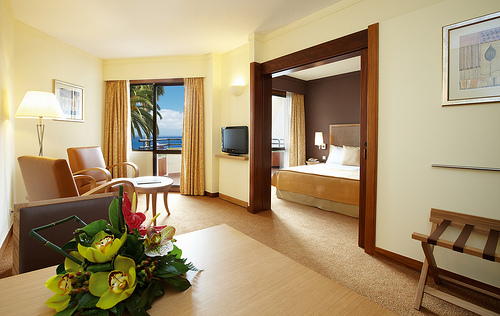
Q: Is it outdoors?
A: Yes, it is outdoors.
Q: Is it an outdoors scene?
A: Yes, it is outdoors.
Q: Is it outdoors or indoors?
A: It is outdoors.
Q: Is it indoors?
A: No, it is outdoors.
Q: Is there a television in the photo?
A: Yes, there is a television.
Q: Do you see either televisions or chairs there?
A: Yes, there is a television.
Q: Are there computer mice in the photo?
A: No, there are no computer mice.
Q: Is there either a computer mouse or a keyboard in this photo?
A: No, there are no computer mice or keyboards.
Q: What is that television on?
A: The television is on the wall.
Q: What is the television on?
A: The television is on the wall.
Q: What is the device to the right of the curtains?
A: The device is a television.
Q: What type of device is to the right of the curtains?
A: The device is a television.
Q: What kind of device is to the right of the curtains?
A: The device is a television.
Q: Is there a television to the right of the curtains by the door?
A: Yes, there is a television to the right of the curtains.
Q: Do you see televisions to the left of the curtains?
A: No, the television is to the right of the curtains.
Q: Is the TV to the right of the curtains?
A: Yes, the TV is to the right of the curtains.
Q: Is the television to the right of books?
A: No, the television is to the right of the curtains.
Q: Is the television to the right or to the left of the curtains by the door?
A: The television is to the right of the curtains.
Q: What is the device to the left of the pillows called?
A: The device is a television.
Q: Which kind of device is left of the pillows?
A: The device is a television.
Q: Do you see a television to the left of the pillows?
A: Yes, there is a television to the left of the pillows.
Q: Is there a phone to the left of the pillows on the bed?
A: No, there is a television to the left of the pillows.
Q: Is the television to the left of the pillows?
A: Yes, the television is to the left of the pillows.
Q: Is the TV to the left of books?
A: No, the TV is to the left of the pillows.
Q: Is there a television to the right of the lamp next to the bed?
A: No, the television is to the left of the lamp.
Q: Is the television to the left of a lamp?
A: Yes, the television is to the left of a lamp.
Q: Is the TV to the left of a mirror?
A: No, the TV is to the left of a lamp.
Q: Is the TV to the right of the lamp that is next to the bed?
A: No, the TV is to the left of the lamp.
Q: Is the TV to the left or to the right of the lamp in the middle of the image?
A: The TV is to the left of the lamp.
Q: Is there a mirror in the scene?
A: No, there are no mirrors.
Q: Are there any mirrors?
A: No, there are no mirrors.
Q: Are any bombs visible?
A: No, there are no bombs.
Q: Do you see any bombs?
A: No, there are no bombs.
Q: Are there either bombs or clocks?
A: No, there are no bombs or clocks.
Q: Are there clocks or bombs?
A: No, there are no bombs or clocks.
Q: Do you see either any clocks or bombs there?
A: No, there are no bombs or clocks.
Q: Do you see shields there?
A: No, there are no shields.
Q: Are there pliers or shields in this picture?
A: No, there are no shields or pliers.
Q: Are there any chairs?
A: Yes, there is a chair.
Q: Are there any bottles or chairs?
A: Yes, there is a chair.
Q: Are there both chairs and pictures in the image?
A: Yes, there are both a chair and a picture.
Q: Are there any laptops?
A: No, there are no laptops.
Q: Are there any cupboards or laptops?
A: No, there are no laptops or cupboards.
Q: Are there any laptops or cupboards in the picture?
A: No, there are no laptops or cupboards.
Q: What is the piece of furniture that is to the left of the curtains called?
A: The piece of furniture is a chair.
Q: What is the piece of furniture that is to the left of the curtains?
A: The piece of furniture is a chair.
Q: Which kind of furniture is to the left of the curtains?
A: The piece of furniture is a chair.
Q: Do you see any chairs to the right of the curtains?
A: No, the chair is to the left of the curtains.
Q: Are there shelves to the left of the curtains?
A: No, there is a chair to the left of the curtains.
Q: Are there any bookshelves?
A: No, there are no bookshelves.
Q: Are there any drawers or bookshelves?
A: No, there are no bookshelves or drawers.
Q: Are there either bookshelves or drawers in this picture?
A: No, there are no bookshelves or drawers.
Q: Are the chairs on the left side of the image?
A: Yes, the chairs are on the left of the image.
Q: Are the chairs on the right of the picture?
A: No, the chairs are on the left of the image.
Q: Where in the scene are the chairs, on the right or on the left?
A: The chairs are on the left of the image.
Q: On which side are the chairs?
A: The chairs are on the left of the image.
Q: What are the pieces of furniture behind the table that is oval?
A: The pieces of furniture are chairs.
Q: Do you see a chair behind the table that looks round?
A: Yes, there are chairs behind the table.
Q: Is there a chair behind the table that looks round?
A: Yes, there are chairs behind the table.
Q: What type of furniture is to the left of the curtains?
A: The pieces of furniture are chairs.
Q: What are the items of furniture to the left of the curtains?
A: The pieces of furniture are chairs.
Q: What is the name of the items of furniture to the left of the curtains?
A: The pieces of furniture are chairs.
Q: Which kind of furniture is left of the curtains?
A: The pieces of furniture are chairs.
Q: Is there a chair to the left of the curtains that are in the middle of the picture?
A: Yes, there are chairs to the left of the curtains.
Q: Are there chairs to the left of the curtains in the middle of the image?
A: Yes, there are chairs to the left of the curtains.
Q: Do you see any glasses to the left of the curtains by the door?
A: No, there are chairs to the left of the curtains.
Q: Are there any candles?
A: No, there are no candles.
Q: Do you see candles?
A: No, there are no candles.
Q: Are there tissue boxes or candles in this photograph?
A: No, there are no candles or tissue boxes.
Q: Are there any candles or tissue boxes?
A: No, there are no candles or tissue boxes.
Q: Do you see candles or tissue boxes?
A: No, there are no candles or tissue boxes.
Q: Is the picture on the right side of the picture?
A: Yes, the picture is on the right of the image.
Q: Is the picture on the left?
A: No, the picture is on the right of the image.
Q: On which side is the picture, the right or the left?
A: The picture is on the right of the image.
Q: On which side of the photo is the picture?
A: The picture is on the right of the image.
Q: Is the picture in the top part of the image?
A: Yes, the picture is in the top of the image.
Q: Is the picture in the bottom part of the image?
A: No, the picture is in the top of the image.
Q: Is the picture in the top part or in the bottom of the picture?
A: The picture is in the top of the image.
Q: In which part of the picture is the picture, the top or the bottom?
A: The picture is in the top of the image.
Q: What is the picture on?
A: The picture is on the wall.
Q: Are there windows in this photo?
A: Yes, there is a window.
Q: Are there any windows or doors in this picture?
A: Yes, there is a window.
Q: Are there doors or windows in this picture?
A: Yes, there is a window.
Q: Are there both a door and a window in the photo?
A: Yes, there are both a window and a door.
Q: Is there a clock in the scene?
A: No, there are no clocks.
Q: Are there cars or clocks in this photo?
A: No, there are no clocks or cars.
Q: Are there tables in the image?
A: Yes, there is a table.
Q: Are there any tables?
A: Yes, there is a table.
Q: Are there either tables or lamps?
A: Yes, there is a table.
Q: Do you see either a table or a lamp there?
A: Yes, there is a table.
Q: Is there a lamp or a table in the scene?
A: Yes, there is a table.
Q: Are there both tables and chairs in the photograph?
A: Yes, there are both a table and a chair.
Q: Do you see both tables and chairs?
A: Yes, there are both a table and a chair.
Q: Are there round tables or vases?
A: Yes, there is a round table.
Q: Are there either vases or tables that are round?
A: Yes, the table is round.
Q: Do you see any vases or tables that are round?
A: Yes, the table is round.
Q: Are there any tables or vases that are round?
A: Yes, the table is round.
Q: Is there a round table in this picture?
A: Yes, there is a round table.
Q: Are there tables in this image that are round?
A: Yes, there is a table that is round.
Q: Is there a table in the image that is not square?
A: Yes, there is a round table.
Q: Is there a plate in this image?
A: No, there are no plates.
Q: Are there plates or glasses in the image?
A: No, there are no plates or glasses.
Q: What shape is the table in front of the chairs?
A: The table is round.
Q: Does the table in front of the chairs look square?
A: No, the table is round.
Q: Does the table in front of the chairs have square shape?
A: No, the table is round.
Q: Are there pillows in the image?
A: Yes, there are pillows.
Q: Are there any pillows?
A: Yes, there are pillows.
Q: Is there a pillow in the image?
A: Yes, there are pillows.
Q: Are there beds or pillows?
A: Yes, there are pillows.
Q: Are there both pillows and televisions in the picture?
A: Yes, there are both pillows and a television.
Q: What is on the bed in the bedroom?
A: The pillows are on the bed.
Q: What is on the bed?
A: The pillows are on the bed.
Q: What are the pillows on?
A: The pillows are on the bed.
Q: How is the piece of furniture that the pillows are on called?
A: The piece of furniture is a bed.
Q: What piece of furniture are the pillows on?
A: The pillows are on the bed.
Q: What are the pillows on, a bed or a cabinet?
A: The pillows are on a bed.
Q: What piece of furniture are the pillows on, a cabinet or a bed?
A: The pillows are on a bed.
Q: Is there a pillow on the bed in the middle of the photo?
A: Yes, there are pillows on the bed.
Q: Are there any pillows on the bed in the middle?
A: Yes, there are pillows on the bed.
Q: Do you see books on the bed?
A: No, there are pillows on the bed.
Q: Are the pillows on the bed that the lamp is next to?
A: Yes, the pillows are on the bed.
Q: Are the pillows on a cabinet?
A: No, the pillows are on the bed.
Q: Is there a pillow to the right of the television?
A: Yes, there are pillows to the right of the television.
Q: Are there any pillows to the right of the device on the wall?
A: Yes, there are pillows to the right of the television.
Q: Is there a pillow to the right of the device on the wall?
A: Yes, there are pillows to the right of the television.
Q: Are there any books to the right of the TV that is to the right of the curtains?
A: No, there are pillows to the right of the television.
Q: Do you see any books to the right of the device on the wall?
A: No, there are pillows to the right of the television.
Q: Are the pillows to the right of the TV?
A: Yes, the pillows are to the right of the TV.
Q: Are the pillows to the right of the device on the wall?
A: Yes, the pillows are to the right of the TV.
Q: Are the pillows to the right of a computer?
A: No, the pillows are to the right of the TV.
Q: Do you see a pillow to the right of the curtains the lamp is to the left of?
A: Yes, there are pillows to the right of the curtains.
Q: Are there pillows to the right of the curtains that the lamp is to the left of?
A: Yes, there are pillows to the right of the curtains.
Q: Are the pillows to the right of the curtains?
A: Yes, the pillows are to the right of the curtains.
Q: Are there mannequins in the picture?
A: No, there are no mannequins.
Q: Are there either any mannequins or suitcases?
A: No, there are no mannequins or suitcases.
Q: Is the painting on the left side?
A: Yes, the painting is on the left of the image.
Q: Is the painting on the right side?
A: No, the painting is on the left of the image.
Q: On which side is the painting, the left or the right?
A: The painting is on the left of the image.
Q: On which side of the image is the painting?
A: The painting is on the left of the image.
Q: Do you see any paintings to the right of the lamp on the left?
A: Yes, there is a painting to the right of the lamp.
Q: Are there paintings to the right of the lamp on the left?
A: Yes, there is a painting to the right of the lamp.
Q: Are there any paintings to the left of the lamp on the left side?
A: No, the painting is to the right of the lamp.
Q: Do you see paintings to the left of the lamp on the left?
A: No, the painting is to the right of the lamp.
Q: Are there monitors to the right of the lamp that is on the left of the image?
A: No, there is a painting to the right of the lamp.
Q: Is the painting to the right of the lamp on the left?
A: Yes, the painting is to the right of the lamp.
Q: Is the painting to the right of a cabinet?
A: No, the painting is to the right of the lamp.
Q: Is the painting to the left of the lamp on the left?
A: No, the painting is to the right of the lamp.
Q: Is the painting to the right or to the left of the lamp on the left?
A: The painting is to the right of the lamp.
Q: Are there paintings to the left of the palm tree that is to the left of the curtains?
A: Yes, there is a painting to the left of the palm tree.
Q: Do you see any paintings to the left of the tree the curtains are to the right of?
A: Yes, there is a painting to the left of the palm tree.